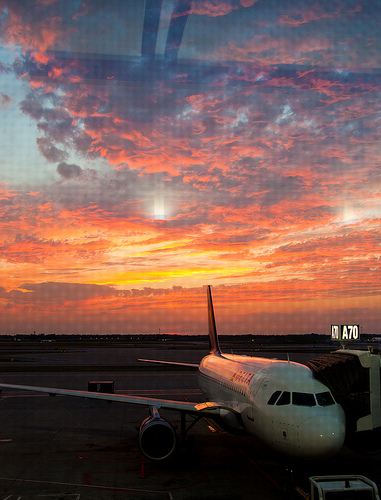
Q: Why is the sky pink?
A: It is sunset.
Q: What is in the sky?
A: Clouds.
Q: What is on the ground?
A: An airplane.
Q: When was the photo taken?
A: In the evening.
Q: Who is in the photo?
A: Nobody.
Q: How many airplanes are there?
A: One.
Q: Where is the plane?
A: On the ground.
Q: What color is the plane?
A: White.